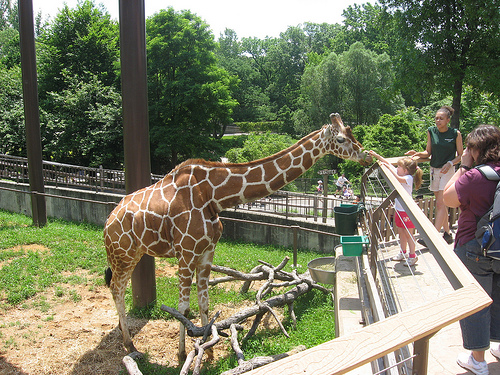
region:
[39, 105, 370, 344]
This is a giraffe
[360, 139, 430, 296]
This is a person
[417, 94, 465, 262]
This is a person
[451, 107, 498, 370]
This is a person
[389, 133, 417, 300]
This is a person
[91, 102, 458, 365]
the girl is petting the giraffe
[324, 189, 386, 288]
these are green baskets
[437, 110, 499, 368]
she is taking a photograph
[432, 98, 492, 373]
this woman is snapping a photo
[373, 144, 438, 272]
she is wearing a pair of red shorts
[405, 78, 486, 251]
she is a zoo employee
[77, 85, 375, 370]
this is a large giraffe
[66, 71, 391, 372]
the giraffe has a long neck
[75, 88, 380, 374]
the giraffe has large brown spots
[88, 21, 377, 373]
a giraffe in a zoo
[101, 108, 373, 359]
Giraffe in an exhibit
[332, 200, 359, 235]
Stacked green trashcans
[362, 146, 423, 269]
Girl feeding a giraffe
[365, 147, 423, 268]
Girl wearing a white shirt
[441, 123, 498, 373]
Woman taking a picture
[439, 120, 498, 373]
Woman wearing a purple shirt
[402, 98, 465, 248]
Woman wearing a dark green shirt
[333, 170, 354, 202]
Person pushing a stroller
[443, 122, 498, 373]
Woman wearing a backpack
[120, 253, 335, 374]
Thick dead branches on the ground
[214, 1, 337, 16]
A clear white sunny sky.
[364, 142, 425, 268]
A little girl in red shorts.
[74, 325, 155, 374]
A giraffe's shadow in the dirt.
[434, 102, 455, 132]
A lady with a big hairdo.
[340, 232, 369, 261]
A green feed container on the ledge.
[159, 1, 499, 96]
The tops of tall green trees.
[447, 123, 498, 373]
A lady taking a picture.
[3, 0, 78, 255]
A zoo cage wooden support pole.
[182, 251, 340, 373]
A piling in giraffe's den.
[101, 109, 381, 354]
A giraffe bending over toward onlookers.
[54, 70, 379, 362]
This is a giraffe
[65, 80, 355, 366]
The animal is brown, yellow, and white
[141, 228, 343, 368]
Branches on the ground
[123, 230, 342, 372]
The branch is light brown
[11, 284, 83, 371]
This is dirt and not grass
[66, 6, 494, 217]
Trees are in the back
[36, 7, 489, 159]
A variety of trees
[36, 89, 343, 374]
Animal is yellow, white, and brown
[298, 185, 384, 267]
Green buckets on the gate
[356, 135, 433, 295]
Kid is a girl